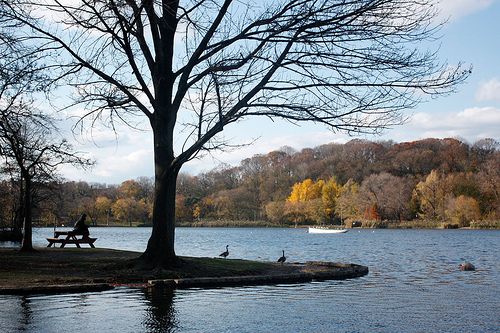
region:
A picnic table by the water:
[46, 222, 101, 247]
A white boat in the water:
[303, 225, 350, 234]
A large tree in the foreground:
[2, 2, 481, 269]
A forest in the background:
[0, 132, 497, 240]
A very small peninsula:
[3, 231, 365, 297]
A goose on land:
[214, 244, 236, 258]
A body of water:
[3, 221, 498, 329]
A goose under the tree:
[274, 249, 289, 264]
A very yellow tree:
[283, 174, 328, 223]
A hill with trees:
[236, 134, 494, 217]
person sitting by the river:
[43, 205, 116, 264]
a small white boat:
[289, 218, 361, 258]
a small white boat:
[297, 199, 369, 244]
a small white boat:
[279, 208, 410, 281]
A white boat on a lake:
[303, 223, 351, 241]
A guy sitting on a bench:
[45, 213, 99, 252]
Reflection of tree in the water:
[122, 271, 190, 331]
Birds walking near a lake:
[215, 243, 290, 268]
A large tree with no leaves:
[1, 1, 474, 201]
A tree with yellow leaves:
[283, 175, 335, 220]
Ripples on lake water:
[329, 285, 495, 329]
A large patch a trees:
[267, 133, 499, 220]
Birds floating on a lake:
[347, 220, 385, 245]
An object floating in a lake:
[450, 255, 482, 278]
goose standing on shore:
[277, 250, 286, 262]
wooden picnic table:
[47, 230, 96, 248]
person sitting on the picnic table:
[73, 212, 90, 238]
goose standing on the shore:
[218, 243, 229, 257]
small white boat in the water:
[307, 225, 348, 233]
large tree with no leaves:
[3, 2, 473, 253]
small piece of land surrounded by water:
[1, 243, 367, 290]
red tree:
[368, 203, 380, 220]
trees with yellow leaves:
[288, 178, 342, 218]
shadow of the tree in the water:
[145, 285, 177, 330]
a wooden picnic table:
[45, 231, 96, 251]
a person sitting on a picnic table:
[42, 213, 99, 253]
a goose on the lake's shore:
[217, 235, 235, 260]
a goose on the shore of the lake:
[275, 248, 289, 263]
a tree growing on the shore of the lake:
[7, 1, 464, 266]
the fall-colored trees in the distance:
[1, 135, 498, 226]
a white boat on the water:
[304, 215, 354, 236]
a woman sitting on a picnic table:
[47, 215, 92, 250]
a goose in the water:
[452, 255, 476, 273]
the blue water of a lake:
[28, 225, 496, 303]